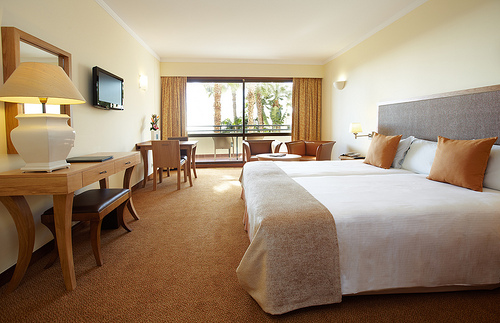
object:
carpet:
[151, 214, 235, 284]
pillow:
[426, 135, 498, 192]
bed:
[235, 159, 499, 312]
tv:
[92, 66, 125, 111]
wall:
[89, 19, 142, 60]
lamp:
[0, 62, 86, 174]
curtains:
[161, 76, 187, 140]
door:
[187, 81, 293, 162]